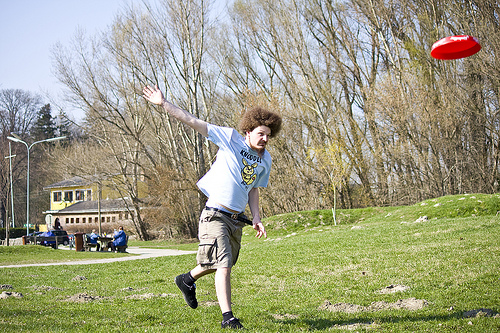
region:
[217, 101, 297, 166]
A man with curly brown hair, beard, and moustache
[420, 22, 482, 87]
A red Frisbee flying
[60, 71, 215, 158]
Trees barren of leaves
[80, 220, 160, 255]
People sitting around a table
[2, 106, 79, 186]
Street lights in a parking lot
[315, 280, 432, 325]
Sand piles in the green grass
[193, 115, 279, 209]
A man in a pale blue shirt throwing a bright red Frisbee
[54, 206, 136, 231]
A long line of small windows in a building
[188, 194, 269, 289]
A man wearing shorts with large pockets on the side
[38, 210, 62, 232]
The back of a stop sign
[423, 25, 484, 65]
A RED FRISBEE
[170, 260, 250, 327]
A PAIR OF BLACK SNEAKERS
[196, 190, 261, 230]
A MAN'S BLACK BELT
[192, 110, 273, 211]
A MAN'S WHITE TEE SHIRT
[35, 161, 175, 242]
TWO BUILDINGS IN THE BACKGROUND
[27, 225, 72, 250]
A CAR IN THE DISTANCE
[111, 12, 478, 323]
A MAN THROWING A FRISBEE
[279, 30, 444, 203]
TREES INN THE BACKGROUND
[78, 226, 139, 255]
PEOPLE SITTING AT A TABLE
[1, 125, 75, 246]
A TALL STREET LAMP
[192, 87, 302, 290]
One man is playing Frisbee.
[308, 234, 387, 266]
Grass is green color.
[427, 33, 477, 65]
Frisbee is red color.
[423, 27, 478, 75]
Frisbee is flying in air.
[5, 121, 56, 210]
Street lamps are attached to the pole.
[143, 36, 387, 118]
Trees are without leaves.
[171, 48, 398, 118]
Trees are behind the man.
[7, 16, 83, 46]
Sky is blue color.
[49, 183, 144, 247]
Building is brown color.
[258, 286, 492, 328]
Shadow falls on ground.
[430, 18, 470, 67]
red flying frisbee in the air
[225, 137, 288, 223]
his white kangaroo t-shirt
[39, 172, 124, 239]
the yellow building in the distance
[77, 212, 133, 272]
people behind him sitting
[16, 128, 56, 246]
tall light poles in the background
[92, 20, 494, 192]
trees without leaves in the background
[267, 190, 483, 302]
green grassy rolling hills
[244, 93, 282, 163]
his curly red hair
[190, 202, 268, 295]
his pants about to fall off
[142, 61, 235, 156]
his arm extended out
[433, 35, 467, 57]
part of a dish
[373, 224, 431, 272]
part some grass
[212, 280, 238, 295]
part of a leg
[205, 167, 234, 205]
part of a blue shirt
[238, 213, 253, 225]
part of a belt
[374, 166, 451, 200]
part of some tree stems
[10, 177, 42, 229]
part of a post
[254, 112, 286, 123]
hair of a ,man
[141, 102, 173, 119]
part of an arm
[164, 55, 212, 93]
part of some tree branches